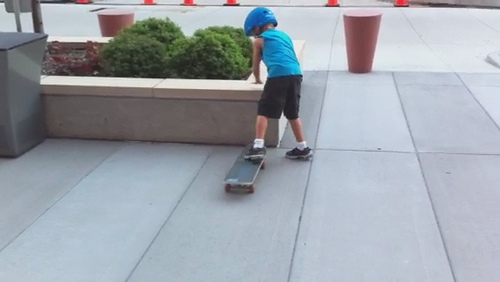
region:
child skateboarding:
[216, 3, 332, 200]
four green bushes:
[102, 7, 262, 94]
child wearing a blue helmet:
[240, 8, 289, 50]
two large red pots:
[97, 3, 405, 82]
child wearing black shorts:
[243, 16, 317, 133]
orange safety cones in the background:
[70, 1, 430, 26]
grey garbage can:
[0, 29, 54, 159]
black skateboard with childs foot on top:
[216, 131, 272, 196]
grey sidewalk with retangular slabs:
[232, 86, 497, 252]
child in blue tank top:
[232, 3, 313, 109]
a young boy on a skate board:
[214, 11, 351, 251]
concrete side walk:
[364, 81, 472, 267]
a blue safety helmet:
[227, 1, 297, 39]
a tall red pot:
[337, 4, 400, 94]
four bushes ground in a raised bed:
[94, 16, 247, 94]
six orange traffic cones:
[72, 0, 442, 15]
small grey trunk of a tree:
[18, 1, 58, 38]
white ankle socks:
[245, 122, 324, 157]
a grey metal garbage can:
[0, 28, 64, 162]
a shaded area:
[391, 70, 476, 277]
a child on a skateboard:
[217, 4, 312, 198]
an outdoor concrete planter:
[31, 32, 313, 154]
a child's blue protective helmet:
[238, 7, 278, 37]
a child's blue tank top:
[255, 29, 305, 78]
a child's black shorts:
[252, 72, 305, 123]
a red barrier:
[334, 7, 384, 74]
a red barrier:
[91, 7, 137, 37]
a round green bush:
[94, 27, 169, 82]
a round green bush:
[168, 29, 250, 83]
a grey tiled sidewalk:
[3, 9, 498, 274]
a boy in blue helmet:
[192, 7, 332, 189]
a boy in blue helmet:
[192, 14, 275, 72]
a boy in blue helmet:
[217, 10, 302, 73]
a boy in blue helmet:
[216, 19, 324, 130]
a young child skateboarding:
[215, 2, 350, 234]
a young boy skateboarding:
[190, 4, 368, 203]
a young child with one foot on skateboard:
[221, 9, 369, 224]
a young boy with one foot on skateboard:
[194, 3, 356, 228]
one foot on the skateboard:
[159, 27, 367, 237]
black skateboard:
[219, 118, 294, 205]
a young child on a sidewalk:
[146, 4, 396, 274]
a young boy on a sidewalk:
[186, 0, 414, 224]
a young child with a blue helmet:
[222, 2, 385, 174]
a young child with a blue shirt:
[224, 7, 374, 150]